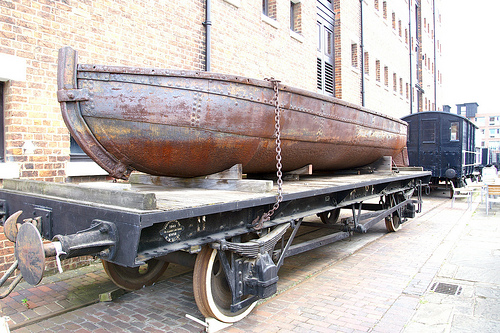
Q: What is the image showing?
A: It is showing a sidewalk.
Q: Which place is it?
A: It is a sidewalk.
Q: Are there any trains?
A: Yes, there is a train.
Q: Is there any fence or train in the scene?
A: Yes, there is a train.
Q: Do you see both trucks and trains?
A: No, there is a train but no trucks.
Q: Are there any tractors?
A: No, there are no tractors.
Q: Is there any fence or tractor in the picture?
A: No, there are no tractors or fences.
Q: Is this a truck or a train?
A: This is a train.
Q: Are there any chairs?
A: Yes, there is a chair.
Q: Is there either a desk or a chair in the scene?
A: Yes, there is a chair.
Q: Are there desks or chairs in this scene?
A: Yes, there is a chair.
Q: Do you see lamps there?
A: No, there are no lamps.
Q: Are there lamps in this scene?
A: No, there are no lamps.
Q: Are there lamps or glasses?
A: No, there are no lamps or glasses.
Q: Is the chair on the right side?
A: Yes, the chair is on the right of the image.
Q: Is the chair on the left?
A: No, the chair is on the right of the image.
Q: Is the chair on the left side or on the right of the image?
A: The chair is on the right of the image.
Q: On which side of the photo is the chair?
A: The chair is on the right of the image.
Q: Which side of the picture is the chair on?
A: The chair is on the right of the image.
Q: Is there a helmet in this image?
A: No, there are no helmets.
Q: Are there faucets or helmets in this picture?
A: No, there are no helmets or faucets.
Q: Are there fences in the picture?
A: No, there are no fences.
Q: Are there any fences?
A: No, there are no fences.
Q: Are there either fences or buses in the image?
A: No, there are no fences or buses.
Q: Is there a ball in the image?
A: No, there are no balls.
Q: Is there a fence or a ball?
A: No, there are no balls or fences.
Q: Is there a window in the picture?
A: Yes, there is a window.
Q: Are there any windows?
A: Yes, there is a window.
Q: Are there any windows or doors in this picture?
A: Yes, there is a window.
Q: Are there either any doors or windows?
A: Yes, there is a window.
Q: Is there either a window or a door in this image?
A: Yes, there is a window.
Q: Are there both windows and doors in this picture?
A: No, there is a window but no doors.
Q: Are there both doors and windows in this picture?
A: No, there is a window but no doors.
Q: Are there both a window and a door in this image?
A: No, there is a window but no doors.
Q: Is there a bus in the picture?
A: No, there are no buses.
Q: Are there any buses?
A: No, there are no buses.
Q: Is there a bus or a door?
A: No, there are no buses or doors.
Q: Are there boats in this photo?
A: Yes, there is a boat.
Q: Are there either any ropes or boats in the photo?
A: Yes, there is a boat.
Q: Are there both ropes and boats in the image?
A: No, there is a boat but no ropes.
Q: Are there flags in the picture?
A: No, there are no flags.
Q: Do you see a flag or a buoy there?
A: No, there are no flags or buoys.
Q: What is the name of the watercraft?
A: The watercraft is a boat.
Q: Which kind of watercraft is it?
A: The watercraft is a boat.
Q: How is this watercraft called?
A: That is a boat.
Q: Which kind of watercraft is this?
A: That is a boat.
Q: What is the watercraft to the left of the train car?
A: The watercraft is a boat.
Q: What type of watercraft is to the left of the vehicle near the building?
A: The watercraft is a boat.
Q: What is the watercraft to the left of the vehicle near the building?
A: The watercraft is a boat.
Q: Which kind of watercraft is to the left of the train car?
A: The watercraft is a boat.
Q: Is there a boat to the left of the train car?
A: Yes, there is a boat to the left of the train car.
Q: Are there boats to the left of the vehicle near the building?
A: Yes, there is a boat to the left of the train car.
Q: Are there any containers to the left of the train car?
A: No, there is a boat to the left of the train car.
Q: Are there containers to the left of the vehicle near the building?
A: No, there is a boat to the left of the train car.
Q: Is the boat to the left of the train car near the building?
A: Yes, the boat is to the left of the train car.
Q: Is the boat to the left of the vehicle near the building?
A: Yes, the boat is to the left of the train car.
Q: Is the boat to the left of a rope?
A: No, the boat is to the left of the train car.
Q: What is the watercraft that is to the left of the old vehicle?
A: The watercraft is a boat.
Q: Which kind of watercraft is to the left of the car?
A: The watercraft is a boat.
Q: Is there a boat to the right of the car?
A: No, the boat is to the left of the car.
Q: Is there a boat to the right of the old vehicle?
A: No, the boat is to the left of the car.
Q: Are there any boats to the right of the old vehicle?
A: No, the boat is to the left of the car.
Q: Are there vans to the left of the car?
A: No, there is a boat to the left of the car.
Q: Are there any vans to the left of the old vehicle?
A: No, there is a boat to the left of the car.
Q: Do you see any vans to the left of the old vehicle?
A: No, there is a boat to the left of the car.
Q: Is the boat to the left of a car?
A: Yes, the boat is to the left of a car.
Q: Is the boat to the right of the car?
A: No, the boat is to the left of the car.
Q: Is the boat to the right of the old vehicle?
A: No, the boat is to the left of the car.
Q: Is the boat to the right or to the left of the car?
A: The boat is to the left of the car.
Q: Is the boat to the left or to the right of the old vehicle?
A: The boat is to the left of the car.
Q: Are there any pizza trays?
A: No, there are no pizza trays.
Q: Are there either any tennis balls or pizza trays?
A: No, there are no pizza trays or tennis balls.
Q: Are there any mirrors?
A: No, there are no mirrors.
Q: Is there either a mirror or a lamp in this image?
A: No, there are no mirrors or lamps.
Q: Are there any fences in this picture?
A: No, there are no fences.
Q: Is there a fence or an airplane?
A: No, there are no fences or airplanes.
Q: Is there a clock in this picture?
A: No, there are no clocks.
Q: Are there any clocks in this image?
A: No, there are no clocks.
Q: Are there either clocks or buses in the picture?
A: No, there are no clocks or buses.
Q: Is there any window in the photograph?
A: Yes, there is a window.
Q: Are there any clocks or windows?
A: Yes, there is a window.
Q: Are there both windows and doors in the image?
A: No, there is a window but no doors.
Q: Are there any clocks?
A: No, there are no clocks.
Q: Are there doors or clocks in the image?
A: No, there are no clocks or doors.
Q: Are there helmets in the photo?
A: No, there are no helmets.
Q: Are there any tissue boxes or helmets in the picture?
A: No, there are no helmets or tissue boxes.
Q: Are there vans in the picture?
A: No, there are no vans.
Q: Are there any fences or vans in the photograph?
A: No, there are no vans or fences.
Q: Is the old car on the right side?
A: Yes, the car is on the right of the image.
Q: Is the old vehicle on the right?
A: Yes, the car is on the right of the image.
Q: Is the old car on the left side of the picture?
A: No, the car is on the right of the image.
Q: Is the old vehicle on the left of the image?
A: No, the car is on the right of the image.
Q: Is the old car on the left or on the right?
A: The car is on the right of the image.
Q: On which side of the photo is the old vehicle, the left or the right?
A: The car is on the right of the image.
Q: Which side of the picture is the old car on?
A: The car is on the right of the image.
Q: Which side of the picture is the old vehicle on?
A: The car is on the right of the image.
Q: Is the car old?
A: Yes, the car is old.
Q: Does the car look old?
A: Yes, the car is old.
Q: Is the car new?
A: No, the car is old.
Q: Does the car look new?
A: No, the car is old.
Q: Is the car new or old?
A: The car is old.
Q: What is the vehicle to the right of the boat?
A: The vehicle is a car.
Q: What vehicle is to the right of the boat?
A: The vehicle is a car.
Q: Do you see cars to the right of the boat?
A: Yes, there is a car to the right of the boat.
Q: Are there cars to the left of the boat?
A: No, the car is to the right of the boat.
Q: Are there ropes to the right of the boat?
A: No, there is a car to the right of the boat.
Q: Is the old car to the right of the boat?
A: Yes, the car is to the right of the boat.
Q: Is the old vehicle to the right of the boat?
A: Yes, the car is to the right of the boat.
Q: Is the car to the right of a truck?
A: No, the car is to the right of the boat.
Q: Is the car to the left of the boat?
A: No, the car is to the right of the boat.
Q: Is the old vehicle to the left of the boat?
A: No, the car is to the right of the boat.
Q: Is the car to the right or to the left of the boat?
A: The car is to the right of the boat.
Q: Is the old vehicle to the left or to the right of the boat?
A: The car is to the right of the boat.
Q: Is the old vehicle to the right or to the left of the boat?
A: The car is to the right of the boat.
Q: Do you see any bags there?
A: No, there are no bags.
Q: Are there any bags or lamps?
A: No, there are no bags or lamps.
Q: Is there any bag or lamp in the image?
A: No, there are no bags or lamps.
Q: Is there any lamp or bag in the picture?
A: No, there are no bags or lamps.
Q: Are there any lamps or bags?
A: No, there are no bags or lamps.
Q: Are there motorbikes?
A: No, there are no motorbikes.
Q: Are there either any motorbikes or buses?
A: No, there are no motorbikes or buses.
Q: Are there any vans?
A: No, there are no vans.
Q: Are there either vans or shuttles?
A: No, there are no vans or shuttles.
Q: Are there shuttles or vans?
A: No, there are no vans or shuttles.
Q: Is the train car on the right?
A: Yes, the train car is on the right of the image.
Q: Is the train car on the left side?
A: No, the train car is on the right of the image.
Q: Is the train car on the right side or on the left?
A: The train car is on the right of the image.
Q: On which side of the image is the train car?
A: The train car is on the right of the image.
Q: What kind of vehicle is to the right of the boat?
A: The vehicle is a train car.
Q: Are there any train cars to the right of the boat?
A: Yes, there is a train car to the right of the boat.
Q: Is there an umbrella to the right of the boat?
A: No, there is a train car to the right of the boat.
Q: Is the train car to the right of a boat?
A: Yes, the train car is to the right of a boat.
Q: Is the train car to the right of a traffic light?
A: No, the train car is to the right of a boat.